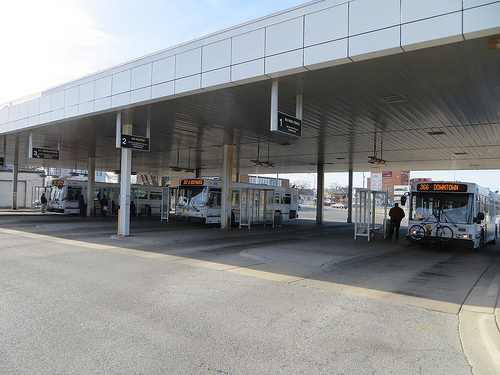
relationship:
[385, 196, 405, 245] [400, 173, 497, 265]
man next to bus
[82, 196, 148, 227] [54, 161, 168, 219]
people near bus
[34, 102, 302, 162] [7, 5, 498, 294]
signs above terminal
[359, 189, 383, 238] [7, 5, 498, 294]
booth at terminal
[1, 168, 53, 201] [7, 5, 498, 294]
garage next to terminal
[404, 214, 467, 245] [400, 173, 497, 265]
bike on bus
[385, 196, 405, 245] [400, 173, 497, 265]
man outside bus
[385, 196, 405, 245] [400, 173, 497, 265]
man near bus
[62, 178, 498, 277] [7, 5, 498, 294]
buses at terminal